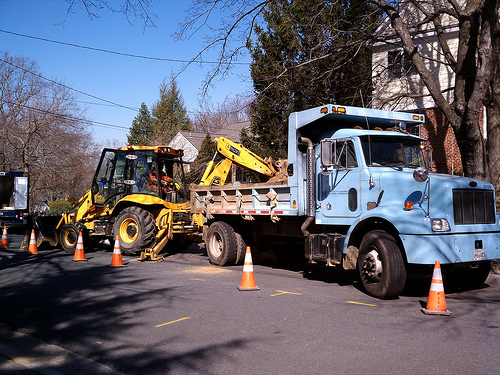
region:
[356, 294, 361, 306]
yellow part of a road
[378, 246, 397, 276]
wheel of a truck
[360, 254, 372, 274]
front wheel of a car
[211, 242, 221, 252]
back wheel of a truck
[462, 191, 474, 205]
front part of a truck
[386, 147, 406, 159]
wind screen of a truck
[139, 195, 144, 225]
big wheel of a car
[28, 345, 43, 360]
edge of a road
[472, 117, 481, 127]
bark of a tree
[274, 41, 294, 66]
branches of a tree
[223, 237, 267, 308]
orange and white safety cones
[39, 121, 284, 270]
yellow bulldozer doing street work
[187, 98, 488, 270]
blue dump truck doing street work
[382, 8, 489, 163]
white house with brick siding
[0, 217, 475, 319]
six orange and white cones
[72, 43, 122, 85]
bright clear blue sky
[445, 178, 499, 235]
black grill on blue dump truck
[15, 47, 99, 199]
trees with no leaves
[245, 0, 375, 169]
tall green tree on side of house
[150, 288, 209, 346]
yellow lines painted in street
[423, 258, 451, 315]
Orange and white traffic cone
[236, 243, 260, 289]
Orange and white traffic cone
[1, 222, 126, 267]
Orange and white traffic cones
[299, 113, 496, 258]
Cab of heavy duty blue truck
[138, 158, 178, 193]
Man operating heavy machinery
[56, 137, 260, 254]
Piece of heavy machinery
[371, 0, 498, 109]
Partial view of house's second story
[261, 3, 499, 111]
Tree with no leaves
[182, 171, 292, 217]
Dirt piled up in bed of truck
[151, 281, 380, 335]
Orange painted lines in road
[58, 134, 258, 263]
yellow bulldozer on street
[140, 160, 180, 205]
man inside of bulldozer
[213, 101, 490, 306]
blue truck on street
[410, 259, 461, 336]
ornage pylon with white stripes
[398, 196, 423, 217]
orange light on fender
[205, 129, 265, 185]
yellow arm of bulldozer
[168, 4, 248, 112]
tree branches with no leaves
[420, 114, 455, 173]
brick surface on building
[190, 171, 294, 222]
bed on back of truck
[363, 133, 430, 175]
windsheild on front of truck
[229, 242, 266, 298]
orange and white caution cone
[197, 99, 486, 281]
large blue dump truck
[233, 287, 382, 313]
yellow markings on the street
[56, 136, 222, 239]
a yellow backhoe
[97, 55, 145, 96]
a clear blue sky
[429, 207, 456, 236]
a shiny white headlight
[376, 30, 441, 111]
a house next to a tree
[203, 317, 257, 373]
gray asphalt on the street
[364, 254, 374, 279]
large bolts in the tire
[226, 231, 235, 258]
thick black treads on a tire